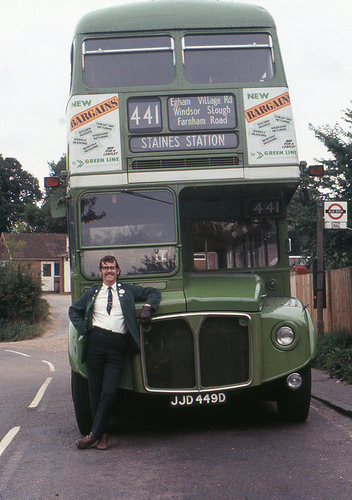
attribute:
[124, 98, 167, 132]
number — 441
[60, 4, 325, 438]
bus — green line, double decker, set to go, green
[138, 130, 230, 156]
route — on the bus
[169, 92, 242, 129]
station — on the bus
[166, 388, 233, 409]
license plate — black, white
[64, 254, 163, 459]
driver — happy, posing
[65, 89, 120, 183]
advertising — a bargain, yellow, black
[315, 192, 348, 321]
sign — on pole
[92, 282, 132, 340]
shirt — white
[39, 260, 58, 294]
door — white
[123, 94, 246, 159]
sign — black